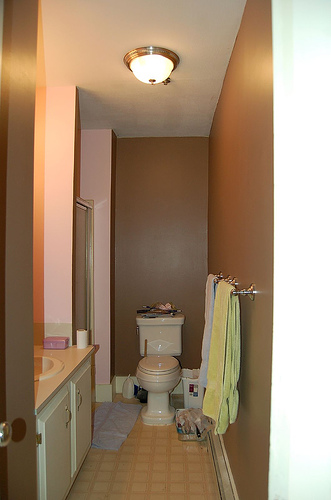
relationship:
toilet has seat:
[137, 323, 179, 427] [141, 367, 179, 378]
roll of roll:
[77, 333, 88, 347] [76, 329, 88, 350]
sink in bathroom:
[36, 360, 54, 375] [75, 81, 249, 438]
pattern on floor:
[112, 466, 128, 482] [143, 464, 211, 490]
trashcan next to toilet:
[184, 378, 203, 406] [137, 323, 179, 427]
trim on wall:
[213, 450, 227, 495] [208, 118, 274, 269]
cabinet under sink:
[50, 427, 74, 490] [36, 360, 54, 375]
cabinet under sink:
[80, 390, 101, 467] [36, 360, 54, 375]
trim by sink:
[39, 327, 61, 332] [36, 360, 54, 375]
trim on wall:
[39, 327, 61, 332] [38, 175, 72, 321]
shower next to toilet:
[80, 212, 92, 329] [137, 323, 179, 427]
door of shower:
[76, 210, 88, 222] [80, 212, 92, 329]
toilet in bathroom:
[137, 323, 179, 427] [75, 81, 249, 438]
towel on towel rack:
[205, 288, 243, 430] [241, 287, 259, 298]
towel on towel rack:
[103, 411, 124, 453] [241, 287, 259, 298]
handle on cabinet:
[69, 408, 71, 419] [50, 427, 74, 490]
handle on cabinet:
[80, 392, 81, 408] [80, 390, 101, 467]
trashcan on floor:
[184, 378, 203, 406] [143, 464, 211, 490]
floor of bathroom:
[143, 464, 211, 490] [75, 81, 249, 438]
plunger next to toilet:
[136, 392, 148, 402] [137, 323, 179, 427]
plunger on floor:
[136, 392, 148, 402] [143, 464, 211, 490]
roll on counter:
[76, 329, 88, 350] [62, 352, 74, 364]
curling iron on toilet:
[150, 308, 173, 316] [137, 323, 179, 427]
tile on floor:
[143, 436, 157, 447] [143, 464, 211, 490]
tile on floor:
[81, 485, 90, 492] [143, 464, 211, 490]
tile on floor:
[143, 447, 153, 455] [143, 464, 211, 490]